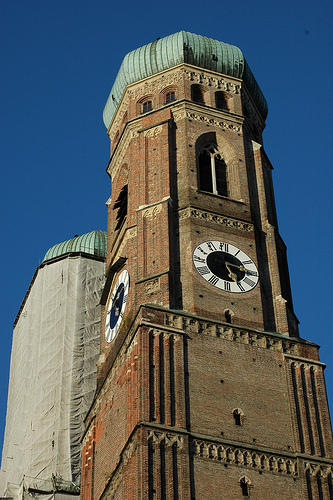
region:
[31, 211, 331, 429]
picture taken outdoors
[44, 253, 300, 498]
picture taken during the day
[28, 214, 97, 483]
construction on a building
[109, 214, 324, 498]
a clock tower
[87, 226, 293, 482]
the tower is made of brick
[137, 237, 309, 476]
the clock tower is old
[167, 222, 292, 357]
the clock has roman numerals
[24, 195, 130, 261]
the sky is clear of clouds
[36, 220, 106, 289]
the top of the building is copper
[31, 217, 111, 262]
the roof is green in color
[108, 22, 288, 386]
A london clock tower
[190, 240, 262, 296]
A clock with roman numbers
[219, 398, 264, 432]
a keyhold shaped window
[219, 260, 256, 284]
Gold clock hands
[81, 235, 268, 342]
Two clocks on tower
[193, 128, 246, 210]
A large double window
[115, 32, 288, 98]
Green roof of clock tower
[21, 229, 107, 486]
a beige cover over building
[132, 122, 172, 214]
left side of clock tower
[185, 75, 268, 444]
Front side of clock tower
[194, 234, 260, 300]
Clock on tower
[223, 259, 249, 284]
Clock's hands are golden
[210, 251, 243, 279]
Center is black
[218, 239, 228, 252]
Roman numeral twelve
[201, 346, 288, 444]
Tower made of bricks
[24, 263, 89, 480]
Construction work on this tower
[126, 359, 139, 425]
Red brick along edges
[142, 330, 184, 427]
Column facades are tall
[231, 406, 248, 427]
Hole in tower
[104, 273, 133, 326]
Second clock nearby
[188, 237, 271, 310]
a clock on the building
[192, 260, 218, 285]
roman numerials.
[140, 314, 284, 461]
the building is brown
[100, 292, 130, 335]
a clock on the side of builing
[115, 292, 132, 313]
roman numerials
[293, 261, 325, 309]
the sky is bright blue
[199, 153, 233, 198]
a window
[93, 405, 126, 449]
building is brown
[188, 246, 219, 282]
roman numerials are black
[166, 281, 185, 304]
shadow on the building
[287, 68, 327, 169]
The sky is blue.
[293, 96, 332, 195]
The sky is clear.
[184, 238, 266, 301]
The clock face is black and white.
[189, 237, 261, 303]
The clock is large.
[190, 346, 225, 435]
The building is brown.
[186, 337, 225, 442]
The building is made of brick.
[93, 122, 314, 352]
The clock is on a tower.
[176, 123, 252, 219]
The tower has windows in it.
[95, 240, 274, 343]
The clock is on each side of the tower.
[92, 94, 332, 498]
The tower is tall.